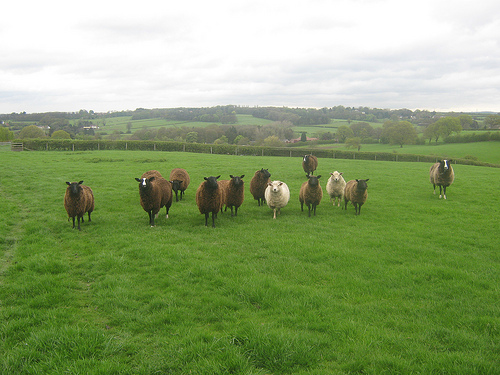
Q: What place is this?
A: It is a field.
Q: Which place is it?
A: It is a field.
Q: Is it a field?
A: Yes, it is a field.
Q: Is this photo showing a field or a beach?
A: It is showing a field.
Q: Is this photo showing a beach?
A: No, the picture is showing a field.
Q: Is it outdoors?
A: Yes, it is outdoors.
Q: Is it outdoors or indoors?
A: It is outdoors.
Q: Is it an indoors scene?
A: No, it is outdoors.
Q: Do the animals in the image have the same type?
A: Yes, all the animals are sheep.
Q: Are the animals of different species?
A: No, all the animals are sheep.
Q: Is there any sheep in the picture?
A: Yes, there is a sheep.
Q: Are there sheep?
A: Yes, there is a sheep.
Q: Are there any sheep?
A: Yes, there is a sheep.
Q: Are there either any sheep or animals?
A: Yes, there is a sheep.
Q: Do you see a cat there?
A: No, there are no cats.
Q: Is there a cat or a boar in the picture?
A: No, there are no cats or boars.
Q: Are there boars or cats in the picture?
A: No, there are no cats or boars.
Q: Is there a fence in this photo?
A: Yes, there is a fence.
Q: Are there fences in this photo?
A: Yes, there is a fence.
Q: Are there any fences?
A: Yes, there is a fence.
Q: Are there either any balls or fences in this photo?
A: Yes, there is a fence.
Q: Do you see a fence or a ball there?
A: Yes, there is a fence.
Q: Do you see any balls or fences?
A: Yes, there is a fence.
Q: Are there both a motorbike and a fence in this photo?
A: No, there is a fence but no motorcycles.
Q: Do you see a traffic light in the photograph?
A: No, there are no traffic lights.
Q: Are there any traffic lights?
A: No, there are no traffic lights.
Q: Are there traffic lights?
A: No, there are no traffic lights.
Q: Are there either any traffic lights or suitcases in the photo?
A: No, there are no traffic lights or suitcases.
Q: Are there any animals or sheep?
A: Yes, there is a sheep.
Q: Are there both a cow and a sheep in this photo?
A: No, there is a sheep but no cows.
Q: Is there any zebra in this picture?
A: No, there are no zebras.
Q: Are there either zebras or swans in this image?
A: No, there are no zebras or swans.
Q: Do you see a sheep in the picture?
A: Yes, there is a sheep.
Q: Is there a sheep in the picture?
A: Yes, there is a sheep.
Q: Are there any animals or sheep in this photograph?
A: Yes, there is a sheep.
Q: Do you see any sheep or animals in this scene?
A: Yes, there is a sheep.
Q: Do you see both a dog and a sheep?
A: No, there is a sheep but no dogs.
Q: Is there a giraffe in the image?
A: No, there are no giraffes.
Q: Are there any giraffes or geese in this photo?
A: No, there are no giraffes or geese.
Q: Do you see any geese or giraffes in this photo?
A: No, there are no giraffes or geese.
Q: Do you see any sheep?
A: Yes, there is a sheep.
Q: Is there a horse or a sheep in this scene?
A: Yes, there is a sheep.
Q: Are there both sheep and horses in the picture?
A: No, there is a sheep but no horses.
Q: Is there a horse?
A: No, there are no horses.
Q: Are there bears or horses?
A: No, there are no horses or bears.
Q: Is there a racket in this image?
A: No, there are no rackets.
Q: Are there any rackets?
A: No, there are no rackets.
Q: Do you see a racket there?
A: No, there are no rackets.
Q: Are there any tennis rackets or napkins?
A: No, there are no tennis rackets or napkins.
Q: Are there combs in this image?
A: No, there are no combs.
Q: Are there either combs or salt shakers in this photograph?
A: No, there are no combs or salt shakers.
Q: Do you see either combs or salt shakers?
A: No, there are no combs or salt shakers.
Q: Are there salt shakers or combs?
A: No, there are no combs or salt shakers.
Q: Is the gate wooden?
A: Yes, the gate is wooden.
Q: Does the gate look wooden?
A: Yes, the gate is wooden.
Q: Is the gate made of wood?
A: Yes, the gate is made of wood.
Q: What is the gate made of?
A: The gate is made of wood.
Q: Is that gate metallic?
A: No, the gate is wooden.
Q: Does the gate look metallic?
A: No, the gate is wooden.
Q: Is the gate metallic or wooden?
A: The gate is wooden.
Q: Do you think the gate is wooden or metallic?
A: The gate is wooden.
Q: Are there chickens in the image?
A: No, there are no chickens.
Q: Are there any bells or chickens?
A: No, there are no chickens or bells.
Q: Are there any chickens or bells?
A: No, there are no chickens or bells.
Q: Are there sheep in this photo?
A: Yes, there is a sheep.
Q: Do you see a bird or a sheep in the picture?
A: Yes, there is a sheep.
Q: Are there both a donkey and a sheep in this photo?
A: No, there is a sheep but no donkeys.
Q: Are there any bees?
A: No, there are no bees.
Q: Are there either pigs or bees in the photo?
A: No, there are no bees or pigs.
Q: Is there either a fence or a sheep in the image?
A: Yes, there is a sheep.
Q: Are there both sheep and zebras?
A: No, there is a sheep but no zebras.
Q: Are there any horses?
A: No, there are no horses.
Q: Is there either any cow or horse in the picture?
A: No, there are no horses or cows.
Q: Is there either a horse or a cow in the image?
A: No, there are no horses or cows.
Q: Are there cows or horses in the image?
A: No, there are no horses or cows.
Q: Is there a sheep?
A: Yes, there is a sheep.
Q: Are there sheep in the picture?
A: Yes, there is a sheep.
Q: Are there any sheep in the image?
A: Yes, there is a sheep.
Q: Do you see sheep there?
A: Yes, there is a sheep.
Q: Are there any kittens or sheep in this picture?
A: Yes, there is a sheep.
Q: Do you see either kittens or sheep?
A: Yes, there is a sheep.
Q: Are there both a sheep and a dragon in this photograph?
A: No, there is a sheep but no dragons.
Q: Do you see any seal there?
A: No, there are no seals.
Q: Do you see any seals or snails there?
A: No, there are no seals or snails.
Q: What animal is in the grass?
A: The animal is a sheep.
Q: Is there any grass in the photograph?
A: Yes, there is grass.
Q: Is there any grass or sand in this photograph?
A: Yes, there is grass.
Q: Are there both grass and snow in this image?
A: No, there is grass but no snow.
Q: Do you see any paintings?
A: No, there are no paintings.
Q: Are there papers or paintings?
A: No, there are no paintings or papers.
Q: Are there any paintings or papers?
A: No, there are no paintings or papers.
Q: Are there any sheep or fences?
A: Yes, there is a sheep.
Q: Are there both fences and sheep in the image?
A: Yes, there are both a sheep and a fence.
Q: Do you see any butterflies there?
A: No, there are no butterflies.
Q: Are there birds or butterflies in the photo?
A: No, there are no butterflies or birds.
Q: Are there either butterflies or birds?
A: No, there are no butterflies or birds.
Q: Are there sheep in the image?
A: Yes, there is a sheep.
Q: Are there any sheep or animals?
A: Yes, there is a sheep.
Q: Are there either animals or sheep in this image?
A: Yes, there is a sheep.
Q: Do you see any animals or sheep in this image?
A: Yes, there is a sheep.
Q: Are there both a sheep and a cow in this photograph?
A: No, there is a sheep but no cows.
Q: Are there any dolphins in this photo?
A: No, there are no dolphins.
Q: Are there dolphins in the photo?
A: No, there are no dolphins.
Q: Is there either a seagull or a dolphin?
A: No, there are no dolphins or seagulls.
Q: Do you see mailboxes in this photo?
A: No, there are no mailboxes.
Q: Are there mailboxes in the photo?
A: No, there are no mailboxes.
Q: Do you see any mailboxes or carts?
A: No, there are no mailboxes or carts.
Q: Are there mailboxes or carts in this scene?
A: No, there are no mailboxes or carts.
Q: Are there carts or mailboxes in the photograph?
A: No, there are no mailboxes or carts.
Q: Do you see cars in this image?
A: No, there are no cars.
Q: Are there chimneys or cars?
A: No, there are no cars or chimneys.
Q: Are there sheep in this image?
A: Yes, there is a sheep.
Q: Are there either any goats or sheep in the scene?
A: Yes, there is a sheep.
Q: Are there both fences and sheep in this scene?
A: Yes, there are both a sheep and a fence.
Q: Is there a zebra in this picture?
A: No, there are no zebras.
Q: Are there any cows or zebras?
A: No, there are no zebras or cows.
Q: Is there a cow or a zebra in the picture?
A: No, there are no zebras or cows.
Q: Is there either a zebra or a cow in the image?
A: No, there are no zebras or cows.